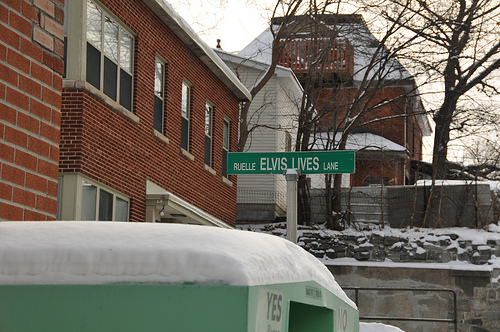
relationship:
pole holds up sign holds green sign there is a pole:
[282, 169, 309, 245] [283, 171, 300, 239]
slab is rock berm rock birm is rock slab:
[330, 258, 498, 331] [307, 222, 499, 332]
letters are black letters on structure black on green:
[262, 288, 287, 326] [1, 281, 359, 332]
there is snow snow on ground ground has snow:
[1, 222, 292, 285] [340, 218, 499, 268]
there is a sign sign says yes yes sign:
[255, 287, 294, 331] [262, 288, 287, 326]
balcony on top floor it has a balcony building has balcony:
[269, 27, 361, 83] [239, 1, 420, 228]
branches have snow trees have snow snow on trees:
[331, 82, 431, 154] [239, 1, 420, 228]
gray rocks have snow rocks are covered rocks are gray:
[232, 215, 498, 290] [340, 218, 499, 268]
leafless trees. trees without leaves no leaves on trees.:
[297, 2, 462, 235] [359, 1, 498, 243]